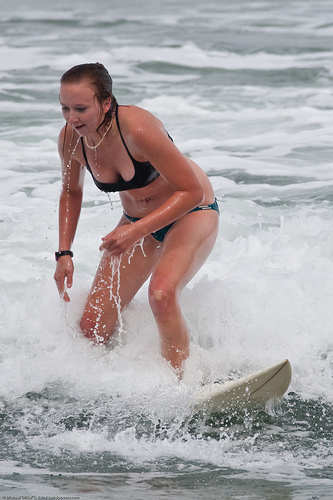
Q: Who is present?
A: A woman.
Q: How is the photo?
A: Clear.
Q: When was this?
A: Daytime.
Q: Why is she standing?
A: To surf.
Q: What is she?
A: A human.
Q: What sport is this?
A: Surfing.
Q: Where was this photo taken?
A: At the beach.